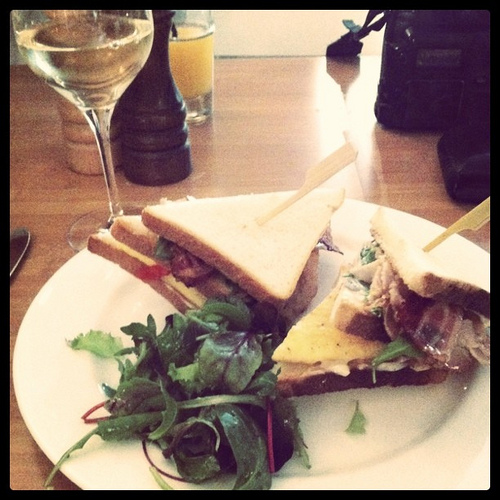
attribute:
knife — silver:
[13, 214, 66, 327]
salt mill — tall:
[14, 7, 158, 252]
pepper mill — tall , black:
[122, 9, 198, 180]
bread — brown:
[207, 209, 238, 244]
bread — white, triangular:
[75, 162, 358, 318]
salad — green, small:
[43, 297, 313, 490]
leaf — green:
[367, 336, 424, 387]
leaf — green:
[341, 394, 371, 438]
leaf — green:
[67, 327, 124, 362]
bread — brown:
[134, 184, 351, 302]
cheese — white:
[281, 299, 391, 370]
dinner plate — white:
[15, 256, 114, 431]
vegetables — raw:
[67, 310, 324, 494]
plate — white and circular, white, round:
[11, 190, 491, 491]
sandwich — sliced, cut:
[83, 183, 490, 397]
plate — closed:
[17, 159, 494, 499]